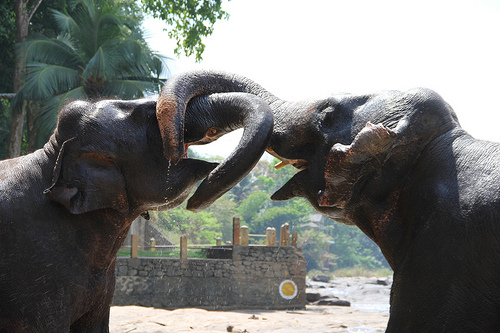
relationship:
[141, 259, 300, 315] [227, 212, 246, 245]
stone wall with wooden post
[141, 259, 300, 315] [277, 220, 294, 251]
stone wall with wooden post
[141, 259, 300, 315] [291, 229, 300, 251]
stone wall with wooden post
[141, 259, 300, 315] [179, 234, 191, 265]
stone wall with wooden post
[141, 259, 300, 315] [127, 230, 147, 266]
stone wall with wooden post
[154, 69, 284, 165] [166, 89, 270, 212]
elephant trunk intertwined with trunk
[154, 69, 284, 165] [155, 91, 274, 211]
elephant trunk intertwined with trunk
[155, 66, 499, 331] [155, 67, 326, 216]
elephant with intertwined trunks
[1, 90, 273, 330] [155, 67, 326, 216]
elephant with intertwined trunks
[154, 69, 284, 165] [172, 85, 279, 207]
elephant trunk intertwined with trunk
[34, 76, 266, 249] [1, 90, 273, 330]
head of elephant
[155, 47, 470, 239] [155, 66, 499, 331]
head of elephant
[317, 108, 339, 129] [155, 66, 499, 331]
eye of elephant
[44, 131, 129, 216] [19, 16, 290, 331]
ear of elephant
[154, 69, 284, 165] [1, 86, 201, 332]
elephant trunk of elephant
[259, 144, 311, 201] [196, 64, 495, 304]
mouth of elephant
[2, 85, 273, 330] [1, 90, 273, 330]
body of elephant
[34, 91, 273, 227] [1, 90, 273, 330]
head of a elephant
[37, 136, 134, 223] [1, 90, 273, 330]
ear of an elephant